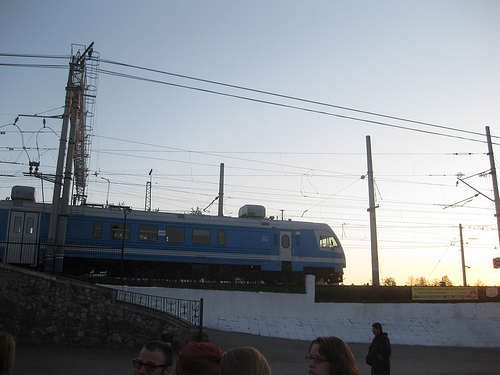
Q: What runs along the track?
A: Power lines.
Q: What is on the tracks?
A: Train.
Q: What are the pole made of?
A: Wood.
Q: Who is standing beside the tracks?
A: A group of people.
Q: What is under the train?
A: Tracks.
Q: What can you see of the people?
A: Heads.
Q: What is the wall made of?
A: Brick.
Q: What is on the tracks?
A: Train.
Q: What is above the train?
A: Sky.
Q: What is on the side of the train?
A: Window.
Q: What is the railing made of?
A: Metal.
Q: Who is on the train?
A: Passengers.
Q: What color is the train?
A: Blue and white.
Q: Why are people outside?
A: The are waiting to board the train.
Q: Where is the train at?
A: On the tracks.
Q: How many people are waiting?
A: 5.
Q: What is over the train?
A: Wires.